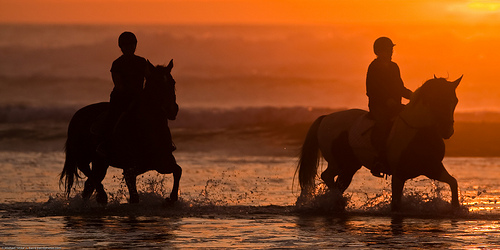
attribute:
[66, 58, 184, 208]
horse — walking, splashing, splashign, behind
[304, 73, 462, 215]
horse — walking, splashing, white, leading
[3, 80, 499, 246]
water — calm, splashing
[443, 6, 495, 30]
sun — setting, yellow, sky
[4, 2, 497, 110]
sky — orange